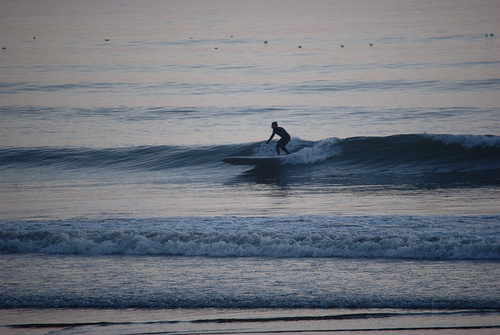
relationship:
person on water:
[268, 120, 289, 156] [0, 0, 499, 309]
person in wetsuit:
[268, 120, 289, 156] [270, 129, 290, 152]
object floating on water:
[299, 45, 305, 48] [0, 0, 499, 309]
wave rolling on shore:
[0, 135, 499, 176] [0, 306, 499, 332]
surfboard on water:
[223, 156, 290, 167] [0, 0, 499, 309]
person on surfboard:
[268, 120, 289, 156] [223, 156, 290, 167]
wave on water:
[0, 135, 499, 176] [0, 0, 499, 309]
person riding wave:
[268, 120, 289, 156] [0, 135, 499, 176]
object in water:
[299, 45, 305, 48] [0, 0, 499, 309]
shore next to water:
[0, 306, 499, 332] [0, 0, 499, 309]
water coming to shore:
[0, 0, 499, 309] [0, 306, 499, 332]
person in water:
[268, 120, 289, 156] [0, 0, 499, 309]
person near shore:
[268, 120, 289, 156] [0, 306, 499, 332]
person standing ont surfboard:
[268, 120, 289, 156] [223, 156, 290, 167]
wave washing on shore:
[0, 135, 499, 176] [0, 306, 499, 332]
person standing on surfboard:
[268, 120, 289, 156] [223, 156, 290, 167]